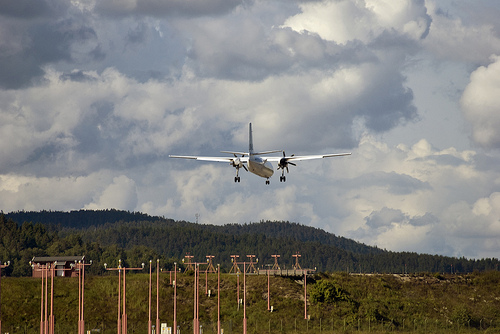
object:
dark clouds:
[0, 0, 443, 242]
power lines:
[300, 272, 309, 320]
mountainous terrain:
[2, 205, 472, 332]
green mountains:
[0, 201, 499, 275]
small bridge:
[261, 266, 314, 278]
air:
[0, 2, 499, 259]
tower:
[194, 212, 203, 224]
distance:
[2, 201, 484, 254]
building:
[28, 254, 90, 277]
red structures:
[287, 251, 302, 269]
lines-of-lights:
[35, 255, 300, 333]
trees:
[450, 302, 473, 328]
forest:
[0, 205, 499, 273]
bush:
[306, 279, 352, 304]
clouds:
[457, 54, 498, 155]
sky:
[1, 0, 495, 260]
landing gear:
[230, 175, 241, 183]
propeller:
[273, 150, 295, 175]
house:
[26, 254, 93, 277]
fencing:
[243, 313, 496, 333]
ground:
[1, 273, 499, 333]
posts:
[47, 270, 55, 333]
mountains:
[44, 219, 499, 274]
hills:
[0, 267, 499, 333]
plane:
[164, 121, 350, 186]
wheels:
[230, 174, 242, 183]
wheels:
[264, 180, 275, 187]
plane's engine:
[273, 156, 293, 172]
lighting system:
[153, 261, 161, 333]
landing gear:
[279, 173, 288, 181]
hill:
[0, 220, 499, 277]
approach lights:
[140, 263, 148, 270]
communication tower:
[194, 212, 202, 226]